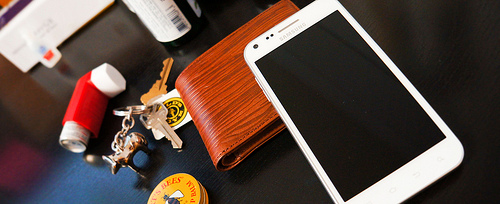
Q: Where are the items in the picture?
A: On a table.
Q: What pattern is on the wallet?
A: Wood grain.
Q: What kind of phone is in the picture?
A: Samsung.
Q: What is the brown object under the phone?
A: A Wallet.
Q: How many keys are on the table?
A: Two.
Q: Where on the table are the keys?
A: Between the wallet and inhaler.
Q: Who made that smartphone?
A: Samsung.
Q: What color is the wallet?
A: Brown.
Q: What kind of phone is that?
A: Smart phone.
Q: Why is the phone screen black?
A: The phone is off.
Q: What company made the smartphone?
A: Samsung.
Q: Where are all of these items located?
A: On a dresser or table.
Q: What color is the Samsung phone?
A: White.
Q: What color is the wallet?
A: Brown.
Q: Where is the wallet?
A: Under the phone.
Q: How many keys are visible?
A: Two.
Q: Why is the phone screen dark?
A: It is off.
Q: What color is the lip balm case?
A: Yellow.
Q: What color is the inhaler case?
A: Red.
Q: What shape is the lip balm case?
A: Round.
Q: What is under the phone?
A: The wallet.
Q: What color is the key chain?
A: Silver.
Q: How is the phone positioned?
A: Laying on a wallet.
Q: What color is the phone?
A: White.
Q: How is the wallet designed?
A: Like wood grain.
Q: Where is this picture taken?
A: On a desk.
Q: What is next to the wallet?
A: Keys and an inhaler.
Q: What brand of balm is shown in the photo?
A: Burt's Bees.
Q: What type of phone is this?
A: A smartphone.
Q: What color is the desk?
A: Brown.